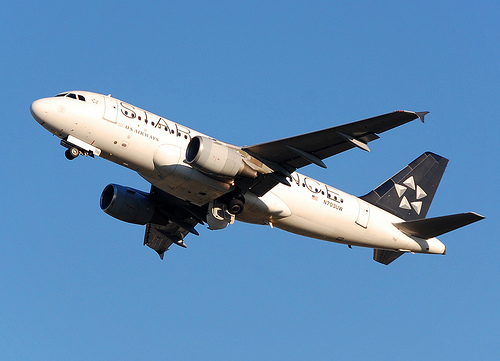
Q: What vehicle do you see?
A: An airplane.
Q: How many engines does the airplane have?
A: Two.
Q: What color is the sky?
A: Blue.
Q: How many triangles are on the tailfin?
A: Five.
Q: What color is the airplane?
A: White and black.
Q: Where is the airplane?
A: In the air.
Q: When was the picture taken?
A: Daytime.